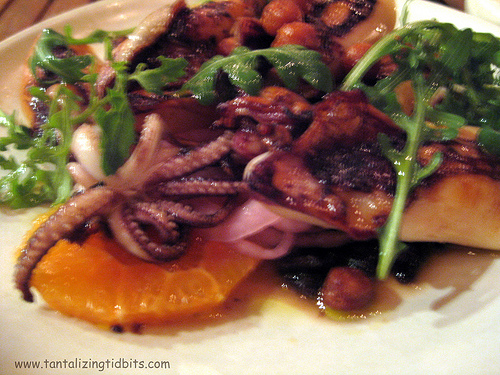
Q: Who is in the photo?
A: No one.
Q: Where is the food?
A: The plate.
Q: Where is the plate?
A: Below the food.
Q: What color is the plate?
A: White.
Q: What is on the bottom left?
A: A website.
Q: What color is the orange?
A: Orange.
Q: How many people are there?
A: None.